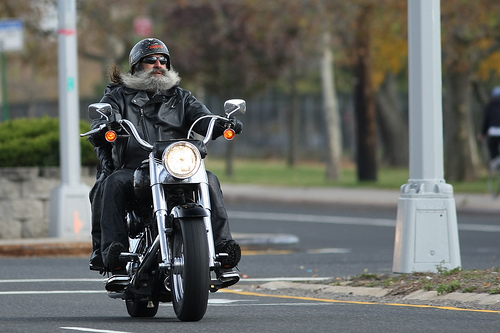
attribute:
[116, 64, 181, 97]
beard — long, grey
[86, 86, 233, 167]
leather jacket — black, shiny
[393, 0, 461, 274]
lamp pole — grey, metal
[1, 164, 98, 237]
brick wall — short, grey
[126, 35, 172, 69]
helmet — black, plastic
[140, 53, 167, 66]
sun glasses — shiny, black, plastic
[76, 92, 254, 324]
motorcycle — shiny, black, silver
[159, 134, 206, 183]
headlight — pale yellow, iluminated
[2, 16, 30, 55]
street sign — white, blue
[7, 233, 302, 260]
curb — stone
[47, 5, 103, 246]
light post — gray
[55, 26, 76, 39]
sticker — red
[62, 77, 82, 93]
sticker — green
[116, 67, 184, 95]
beard — long, gray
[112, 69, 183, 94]
beard — long, gray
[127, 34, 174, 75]
motorcycle helmet — black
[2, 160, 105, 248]
wall — brick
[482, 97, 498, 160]
outfit — dark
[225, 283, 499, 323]
line — yellow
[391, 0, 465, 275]
light post — gray